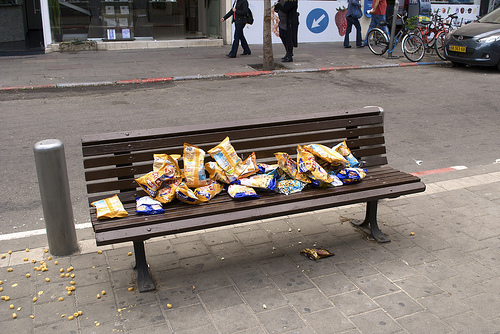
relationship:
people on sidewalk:
[225, 4, 385, 51] [134, 38, 214, 71]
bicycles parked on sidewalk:
[365, 11, 426, 63] [155, 49, 223, 69]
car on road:
[443, 3, 500, 70] [365, 78, 449, 102]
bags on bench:
[91, 134, 366, 218] [81, 100, 427, 295]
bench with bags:
[81, 100, 427, 295] [91, 134, 366, 218]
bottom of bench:
[131, 235, 157, 292] [81, 100, 427, 295]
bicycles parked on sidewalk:
[365, 10, 461, 61] [1, 41, 450, 92]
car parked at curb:
[443, 3, 500, 70] [2, 59, 453, 92]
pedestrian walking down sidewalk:
[218, 0, 253, 59] [1, 41, 450, 92]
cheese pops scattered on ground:
[0, 227, 415, 326] [2, 41, 499, 331]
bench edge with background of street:
[80, 105, 382, 144] [1, 44, 496, 331]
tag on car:
[445, 44, 465, 53] [443, 5, 498, 71]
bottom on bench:
[131, 235, 157, 292] [81, 100, 427, 295]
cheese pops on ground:
[0, 227, 415, 326] [2, 41, 499, 331]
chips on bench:
[92, 137, 363, 219] [81, 100, 427, 295]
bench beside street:
[81, 100, 427, 295] [1, 44, 496, 331]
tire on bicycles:
[399, 32, 426, 62] [403, 17, 452, 60]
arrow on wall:
[308, 14, 327, 30] [229, 0, 379, 41]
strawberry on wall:
[335, 6, 349, 36] [230, 3, 375, 43]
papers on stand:
[103, 4, 131, 38] [100, 5, 135, 41]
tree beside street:
[262, 1, 275, 70] [1, 61, 498, 255]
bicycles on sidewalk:
[368, 9, 457, 60] [1, 41, 450, 92]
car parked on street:
[443, 5, 498, 71] [1, 61, 498, 255]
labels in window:
[104, 5, 131, 40] [50, 1, 220, 42]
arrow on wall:
[310, 14, 326, 30] [224, 2, 370, 44]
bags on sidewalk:
[91, 134, 366, 218] [1, 162, 499, 330]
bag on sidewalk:
[135, 194, 164, 215] [1, 162, 499, 330]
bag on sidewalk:
[225, 182, 258, 201] [1, 162, 499, 330]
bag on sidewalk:
[234, 173, 277, 190] [1, 162, 499, 330]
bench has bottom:
[81, 100, 427, 295] [131, 235, 157, 292]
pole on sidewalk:
[34, 137, 76, 257] [1, 162, 499, 330]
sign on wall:
[305, 8, 328, 33] [224, 2, 370, 44]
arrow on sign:
[310, 14, 326, 30] [305, 8, 328, 33]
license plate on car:
[449, 42, 466, 52] [443, 5, 498, 71]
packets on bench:
[90, 134, 368, 219] [81, 100, 427, 295]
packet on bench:
[273, 178, 306, 193] [81, 100, 427, 295]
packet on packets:
[334, 139, 360, 168] [90, 134, 368, 219]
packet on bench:
[272, 150, 314, 184] [81, 100, 427, 295]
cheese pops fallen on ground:
[1, 221, 415, 331] [2, 41, 499, 331]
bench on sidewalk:
[81, 100, 427, 295] [1, 162, 499, 330]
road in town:
[1, 62, 499, 251] [2, 0, 499, 331]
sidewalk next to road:
[1, 162, 499, 330] [1, 62, 499, 251]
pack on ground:
[302, 246, 337, 260] [2, 41, 499, 331]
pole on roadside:
[34, 137, 76, 257] [2, 62, 499, 250]